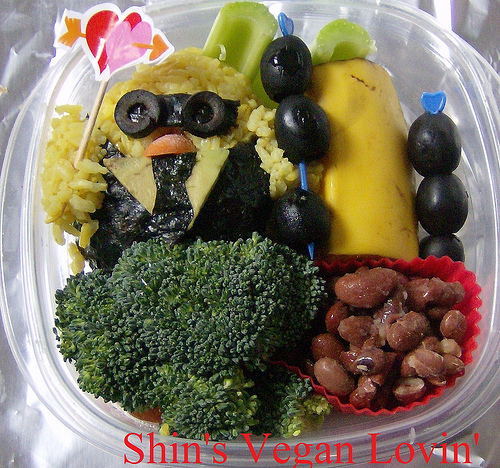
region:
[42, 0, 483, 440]
the food in the container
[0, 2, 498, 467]
the clear container holding the food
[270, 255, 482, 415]
the red silicone cupcake cup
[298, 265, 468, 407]
the beans in the red silicone cup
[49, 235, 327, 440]
the pile of broccoli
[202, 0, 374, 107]
the pieces of celery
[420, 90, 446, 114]
the small blue heart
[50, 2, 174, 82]
the sticker with hearts and an arrow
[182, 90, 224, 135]
the slice of olive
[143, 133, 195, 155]
the small piece of carrot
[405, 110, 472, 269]
Three black olives.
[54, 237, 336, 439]
A bunch of broccoli together on a plate.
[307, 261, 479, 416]
Brown beans in a paper cup.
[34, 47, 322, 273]
Yellow rice on a plate.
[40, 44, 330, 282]
Food made to look like a penguin.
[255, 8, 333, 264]
Olives with a toothpick in between them.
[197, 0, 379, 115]
Multiple pieces of celery.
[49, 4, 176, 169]
A heart on a stick.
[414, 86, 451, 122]
A small blue heart stuck in an olive.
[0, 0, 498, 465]
A clear container full of food.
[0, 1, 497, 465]
plastic food container is packed full of food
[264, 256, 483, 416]
red silicone cupcake wrapper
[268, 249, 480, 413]
silicone cup is holding a small amount of beans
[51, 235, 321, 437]
broccoli shoved into the left hand bottom corner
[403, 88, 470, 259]
black olives are on a blue plastic toothpick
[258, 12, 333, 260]
blue plastic heart toothpick holding olives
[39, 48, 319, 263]
rice formed to look like a chickens body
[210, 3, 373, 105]
cellery pieces in top of bowl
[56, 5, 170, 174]
valentines heart paper toothpick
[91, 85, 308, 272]
pieces of food form suit and eyes on rice chicken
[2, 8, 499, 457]
clear plastic dish holding food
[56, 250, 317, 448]
broccoli on plastic dish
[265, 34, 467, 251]
black olives in the plastic container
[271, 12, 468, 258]
blue toothpicks olives are on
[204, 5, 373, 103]
pieces of celery stalk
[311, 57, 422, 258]
half of a banana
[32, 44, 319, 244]
yellow rice made into bird shape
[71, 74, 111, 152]
toothpick in hand of rice bird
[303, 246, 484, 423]
red cup beans are in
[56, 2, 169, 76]
heart sticker on toothpick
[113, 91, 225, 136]
sliced black olives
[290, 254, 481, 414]
red cup holding beans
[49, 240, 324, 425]
top of green broccoli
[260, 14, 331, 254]
blue toothpick with black olives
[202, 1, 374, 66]
sticks of celery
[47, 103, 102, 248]
yellow rice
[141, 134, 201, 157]
a small carrot slice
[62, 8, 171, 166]
a toothpick with paper hearts on it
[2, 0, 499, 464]
plastic dish full of food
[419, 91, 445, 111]
a blue plastic heart